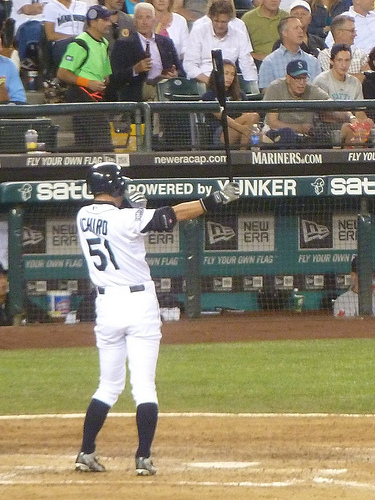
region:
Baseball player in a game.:
[74, 155, 239, 473]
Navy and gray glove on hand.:
[194, 180, 242, 215]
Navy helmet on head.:
[85, 160, 131, 205]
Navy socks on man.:
[75, 396, 159, 464]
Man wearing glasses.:
[266, 53, 332, 133]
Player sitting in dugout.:
[324, 257, 373, 317]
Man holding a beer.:
[110, 2, 176, 97]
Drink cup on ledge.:
[24, 129, 41, 151]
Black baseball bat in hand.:
[204, 47, 243, 195]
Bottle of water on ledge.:
[249, 121, 265, 153]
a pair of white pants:
[91, 286, 162, 407]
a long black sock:
[81, 396, 107, 453]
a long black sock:
[133, 401, 159, 459]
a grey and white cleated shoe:
[73, 449, 104, 472]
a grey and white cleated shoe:
[134, 453, 157, 474]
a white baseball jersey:
[74, 200, 157, 282]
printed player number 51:
[85, 235, 120, 274]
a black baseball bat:
[208, 45, 232, 183]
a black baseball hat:
[84, 160, 131, 194]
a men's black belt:
[97, 284, 146, 295]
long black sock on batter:
[78, 396, 110, 453]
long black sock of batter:
[134, 400, 160, 457]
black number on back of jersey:
[85, 235, 119, 272]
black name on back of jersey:
[77, 215, 108, 235]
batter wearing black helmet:
[83, 160, 132, 198]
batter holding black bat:
[209, 47, 234, 183]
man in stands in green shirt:
[58, 28, 112, 86]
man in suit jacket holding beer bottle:
[142, 39, 151, 62]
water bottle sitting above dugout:
[247, 122, 260, 149]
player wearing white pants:
[88, 278, 164, 406]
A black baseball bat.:
[208, 48, 238, 194]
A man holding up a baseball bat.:
[71, 47, 246, 475]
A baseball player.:
[68, 158, 241, 478]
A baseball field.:
[0, 320, 373, 496]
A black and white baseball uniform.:
[70, 201, 178, 466]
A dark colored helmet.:
[84, 161, 130, 195]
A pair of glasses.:
[291, 75, 310, 79]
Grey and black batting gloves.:
[132, 187, 247, 209]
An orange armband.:
[74, 73, 90, 88]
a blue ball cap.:
[84, 6, 117, 17]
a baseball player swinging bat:
[74, 46, 240, 476]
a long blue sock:
[82, 399, 109, 452]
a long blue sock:
[133, 404, 158, 457]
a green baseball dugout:
[0, 176, 374, 322]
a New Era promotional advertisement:
[201, 212, 273, 264]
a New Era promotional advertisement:
[295, 214, 360, 262]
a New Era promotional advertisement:
[145, 223, 181, 266]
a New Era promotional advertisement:
[21, 216, 84, 270]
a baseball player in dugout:
[331, 257, 358, 317]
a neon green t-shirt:
[59, 31, 112, 82]